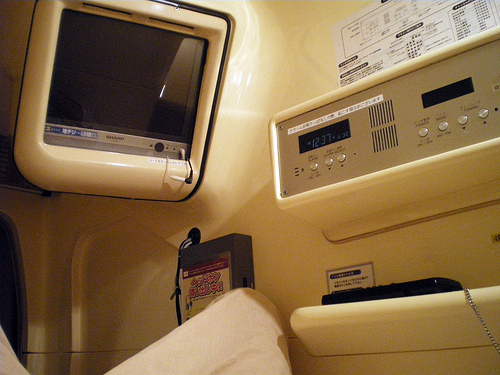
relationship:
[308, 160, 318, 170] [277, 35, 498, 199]
button on a machine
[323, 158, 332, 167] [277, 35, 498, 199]
button on a machine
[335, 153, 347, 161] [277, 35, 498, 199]
button on a machine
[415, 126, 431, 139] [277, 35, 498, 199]
button on a machine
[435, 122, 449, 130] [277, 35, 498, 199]
button on a machine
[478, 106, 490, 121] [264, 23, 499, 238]
button on a controls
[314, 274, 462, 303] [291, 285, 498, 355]
black remote on counter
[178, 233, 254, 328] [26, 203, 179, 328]
box in wall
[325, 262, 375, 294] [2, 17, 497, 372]
cover on wall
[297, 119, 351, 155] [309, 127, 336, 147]
clock has lights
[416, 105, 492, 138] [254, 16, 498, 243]
four buttons on machine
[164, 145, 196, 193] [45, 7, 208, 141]
cords hanging down from screen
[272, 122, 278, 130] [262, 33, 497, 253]
screw in wall box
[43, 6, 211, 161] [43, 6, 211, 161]
display on display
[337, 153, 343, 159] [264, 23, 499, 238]
button on controls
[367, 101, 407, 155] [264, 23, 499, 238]
speaker on controls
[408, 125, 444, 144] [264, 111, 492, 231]
button on radio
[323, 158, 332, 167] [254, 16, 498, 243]
button on a machine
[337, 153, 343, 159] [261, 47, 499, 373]
button on a machine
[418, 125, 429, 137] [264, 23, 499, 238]
button on a controls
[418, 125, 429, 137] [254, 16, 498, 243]
button on a machine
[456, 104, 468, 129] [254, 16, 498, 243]
button on a machine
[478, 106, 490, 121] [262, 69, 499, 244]
button on a machine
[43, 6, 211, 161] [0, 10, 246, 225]
display of a machine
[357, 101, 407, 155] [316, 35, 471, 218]
speaker of a machine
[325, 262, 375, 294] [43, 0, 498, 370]
cover to a wall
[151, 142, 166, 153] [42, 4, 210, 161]
sensor in display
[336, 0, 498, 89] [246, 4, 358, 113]
diagram attached to wall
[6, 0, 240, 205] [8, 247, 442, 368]
machine over bed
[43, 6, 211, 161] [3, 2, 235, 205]
display of monitor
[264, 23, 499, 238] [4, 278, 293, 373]
controls over bed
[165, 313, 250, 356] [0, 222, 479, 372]
pillow of bed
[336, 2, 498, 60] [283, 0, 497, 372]
diagram on wall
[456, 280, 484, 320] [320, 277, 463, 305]
cord attached to black remote